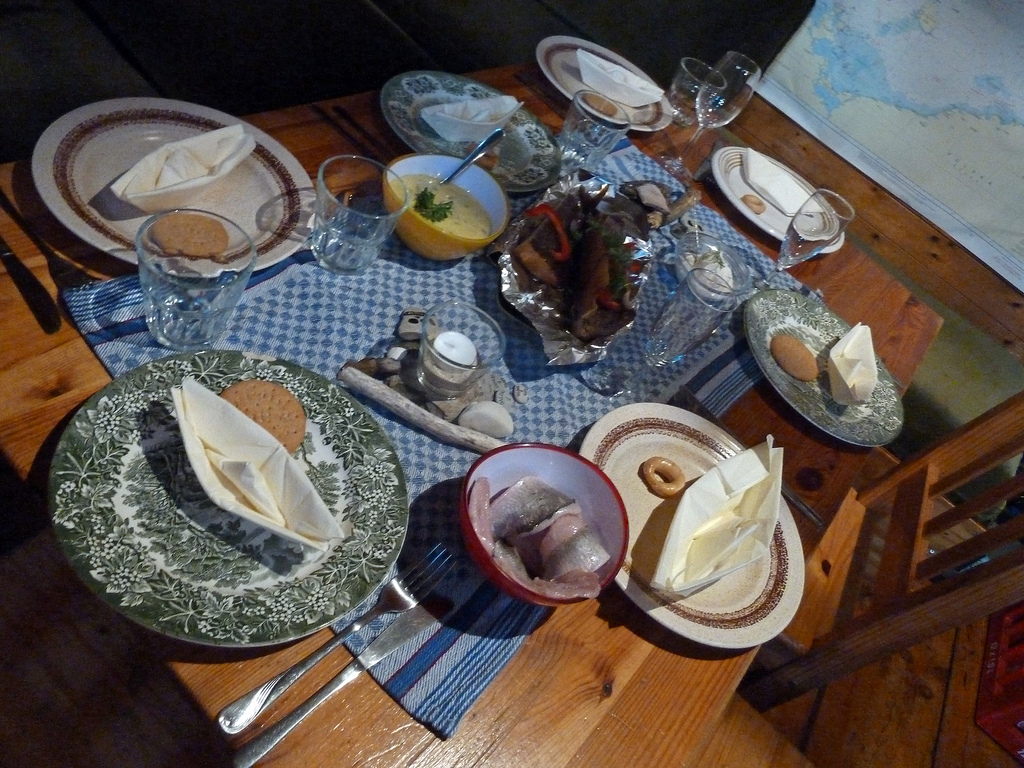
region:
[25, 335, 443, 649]
Plate with cookie and napkin on it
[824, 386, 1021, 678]
Wooden chair at table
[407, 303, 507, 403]
Tea candle in glass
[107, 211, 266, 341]
Empty clear rocks glass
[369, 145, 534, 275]
Yellow bowl containing sauce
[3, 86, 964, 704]
wooden table set for dinner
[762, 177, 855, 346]
Empty clear champagne glass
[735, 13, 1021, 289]
Map hanging on wooden wall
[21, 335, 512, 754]
Place setting on a table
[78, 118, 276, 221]
Napkin folded like a sailboat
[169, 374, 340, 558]
a white paper napkin shaped like a boat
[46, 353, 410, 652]
a green and white round plate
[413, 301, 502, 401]
a votive candle in a small glass cup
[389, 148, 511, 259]
a yellow bowl with soup and parsley on top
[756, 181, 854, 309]
an empty glass of wine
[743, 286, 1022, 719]
a wooden chair in front of a green and white plate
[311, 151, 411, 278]
an empty glass of water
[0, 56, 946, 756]
a blue table mat on a wooden table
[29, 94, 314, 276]
a cookie sitting on a white and red plate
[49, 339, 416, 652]
plate with white and green decorations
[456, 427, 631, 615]
red-rimmed bowl with food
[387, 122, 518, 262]
yellow bowl with spoon inside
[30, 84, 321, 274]
cookie on white and brown plate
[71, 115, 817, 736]
blue checkered tablecloth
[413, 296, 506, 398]
white tealight candle in glass holder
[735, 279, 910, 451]
folded napkin on green plate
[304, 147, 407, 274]
empty tumbler glass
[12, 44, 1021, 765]
a scene inside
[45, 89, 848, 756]
a blue table cloth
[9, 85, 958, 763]
a brown table and chairs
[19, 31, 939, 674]
a few white plates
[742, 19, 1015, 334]
a map in background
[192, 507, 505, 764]
a fork and knife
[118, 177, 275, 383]
a clear glass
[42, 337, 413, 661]
green and white ceramic plate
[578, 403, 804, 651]
white plate with brown trim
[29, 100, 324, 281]
white plate with brown trim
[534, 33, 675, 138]
white plate with brown trim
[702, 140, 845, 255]
white plate with brown trim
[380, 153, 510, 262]
yellow and white serving bowl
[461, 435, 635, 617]
red and white serving bowl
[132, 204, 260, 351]
empty clear drinking glass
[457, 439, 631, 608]
a round bowl with a white interior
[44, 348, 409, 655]
a round green and white plate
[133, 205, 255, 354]
a clear empty glass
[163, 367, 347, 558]
a folded paper napkin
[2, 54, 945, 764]
a brown wooden table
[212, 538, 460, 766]
a silver metal knife and fork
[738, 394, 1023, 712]
a brown wooden chair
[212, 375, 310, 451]
a round brown cookie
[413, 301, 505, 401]
a candle in a clear glass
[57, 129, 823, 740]
a blue table runner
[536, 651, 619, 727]
a wooden table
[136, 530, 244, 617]
design on the plate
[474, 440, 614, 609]
a red bowl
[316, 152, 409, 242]
a small glass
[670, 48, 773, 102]
two wine glasses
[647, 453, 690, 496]
food on the plate